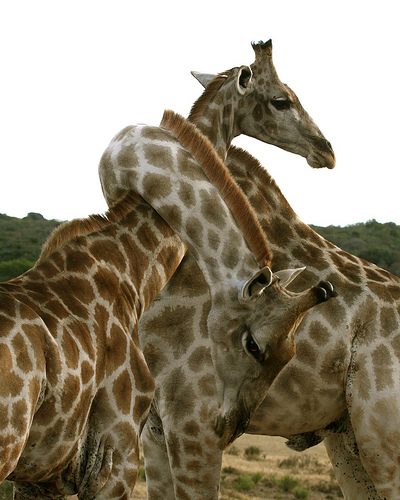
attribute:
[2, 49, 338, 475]
giraffe — spotted, brown, white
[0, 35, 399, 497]
giraffes — white, brown, spotted, male, fighting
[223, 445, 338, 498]
sand — brown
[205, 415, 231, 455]
lip — prehensile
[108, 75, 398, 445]
giraffe — male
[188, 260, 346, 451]
giraffe — tall, white, brown, spotted, bent over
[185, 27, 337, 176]
giraffe — white, brown, spotted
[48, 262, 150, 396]
pattern — spotted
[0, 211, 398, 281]
hill — rocky, green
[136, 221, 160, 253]
spot — brown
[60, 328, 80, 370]
spot — brown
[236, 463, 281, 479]
ground — sandy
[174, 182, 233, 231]
spot — brown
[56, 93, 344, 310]
necks — around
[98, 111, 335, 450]
giraffe — bent over, white, brown, spotted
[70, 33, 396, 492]
giraffe — looking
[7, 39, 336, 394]
giraffe — keeping, bald-topped, male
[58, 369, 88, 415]
spot — brown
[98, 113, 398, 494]
giraffe — brown, white, spotted, male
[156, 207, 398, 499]
giraffe — bald-topped, male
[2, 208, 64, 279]
trees — green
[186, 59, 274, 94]
ears — white, brown, small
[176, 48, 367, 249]
giraffe — tall, white, brown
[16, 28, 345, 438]
giraffes — standing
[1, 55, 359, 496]
giraffe — spotted, white, brown, tall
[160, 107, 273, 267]
mane — brown colored, thick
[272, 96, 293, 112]
eye — open, black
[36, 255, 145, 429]
side — spotted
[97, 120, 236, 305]
neck — long